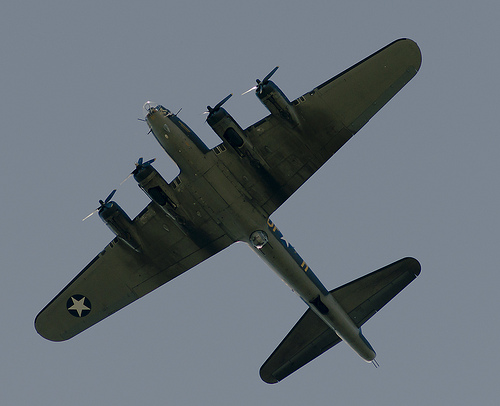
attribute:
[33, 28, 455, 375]
plane — gray, old, vgray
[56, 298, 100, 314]
logo — blue